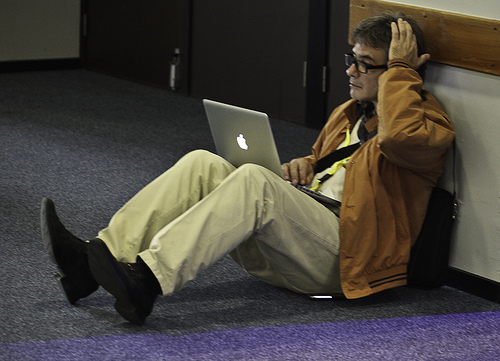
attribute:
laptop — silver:
[201, 98, 342, 207]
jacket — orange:
[306, 59, 455, 299]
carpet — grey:
[2, 70, 500, 360]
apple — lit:
[236, 135, 248, 152]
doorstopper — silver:
[168, 47, 185, 93]